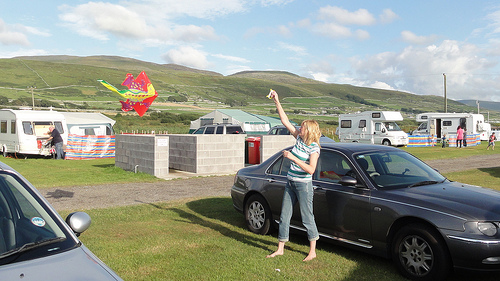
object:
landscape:
[0, 0, 497, 279]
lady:
[265, 88, 322, 260]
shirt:
[454, 128, 463, 140]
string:
[264, 88, 276, 99]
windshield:
[353, 150, 450, 187]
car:
[229, 141, 499, 280]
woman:
[455, 125, 465, 149]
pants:
[278, 179, 320, 242]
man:
[43, 126, 65, 160]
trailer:
[0, 109, 69, 158]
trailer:
[187, 125, 249, 135]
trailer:
[411, 113, 492, 142]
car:
[0, 161, 126, 280]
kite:
[97, 69, 159, 118]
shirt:
[287, 134, 321, 182]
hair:
[299, 119, 322, 149]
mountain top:
[1, 55, 226, 75]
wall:
[195, 135, 247, 174]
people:
[455, 125, 465, 149]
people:
[485, 131, 497, 150]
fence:
[65, 134, 117, 160]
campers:
[333, 109, 408, 147]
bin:
[244, 135, 260, 164]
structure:
[113, 134, 295, 180]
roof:
[213, 109, 265, 124]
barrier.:
[113, 134, 170, 178]